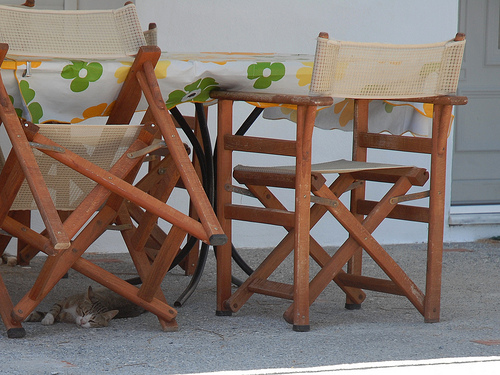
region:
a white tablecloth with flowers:
[2, 43, 457, 144]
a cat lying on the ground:
[44, 277, 154, 330]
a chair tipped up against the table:
[1, 4, 230, 334]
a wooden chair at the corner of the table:
[212, 31, 464, 331]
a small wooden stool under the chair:
[233, 158, 432, 329]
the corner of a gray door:
[446, 1, 498, 206]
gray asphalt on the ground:
[1, 241, 498, 373]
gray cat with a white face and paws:
[16, 280, 161, 334]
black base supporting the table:
[123, 88, 273, 313]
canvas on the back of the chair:
[307, 32, 467, 99]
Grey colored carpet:
[2, 239, 497, 356]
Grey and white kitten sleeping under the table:
[17, 258, 189, 329]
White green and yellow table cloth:
[2, 43, 476, 140]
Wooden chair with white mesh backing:
[209, 26, 460, 328]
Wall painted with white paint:
[15, 8, 449, 243]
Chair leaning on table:
[2, 5, 229, 335]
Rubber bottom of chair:
[205, 229, 230, 249]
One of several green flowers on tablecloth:
[242, 53, 289, 97]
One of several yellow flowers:
[112, 46, 169, 86]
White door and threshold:
[459, 3, 499, 271]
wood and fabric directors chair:
[209, 31, 470, 336]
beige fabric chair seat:
[234, 156, 413, 178]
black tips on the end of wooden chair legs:
[210, 298, 363, 333]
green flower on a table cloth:
[243, 56, 286, 88]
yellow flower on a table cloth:
[291, 62, 315, 88]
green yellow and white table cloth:
[3, 51, 441, 146]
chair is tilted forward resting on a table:
[1, 3, 228, 346]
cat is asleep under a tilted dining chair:
[19, 273, 159, 338]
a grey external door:
[447, 4, 498, 219]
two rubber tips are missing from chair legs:
[6, 226, 234, 343]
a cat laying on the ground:
[42, 271, 149, 343]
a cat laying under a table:
[46, 262, 156, 342]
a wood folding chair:
[220, 24, 458, 341]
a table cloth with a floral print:
[134, 53, 279, 110]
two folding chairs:
[0, 22, 471, 279]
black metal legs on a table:
[170, 91, 266, 303]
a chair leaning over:
[17, 19, 205, 294]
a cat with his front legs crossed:
[33, 294, 73, 337]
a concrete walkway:
[10, 235, 487, 373]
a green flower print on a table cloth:
[237, 51, 288, 97]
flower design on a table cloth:
[55, 55, 106, 98]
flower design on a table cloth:
[67, 96, 113, 125]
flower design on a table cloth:
[162, 70, 223, 110]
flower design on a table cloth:
[243, 55, 285, 92]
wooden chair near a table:
[215, 26, 473, 333]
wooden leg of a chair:
[284, 103, 330, 336]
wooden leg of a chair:
[415, 102, 461, 325]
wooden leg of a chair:
[212, 98, 238, 325]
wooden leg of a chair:
[0, 85, 85, 257]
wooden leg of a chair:
[135, 72, 238, 253]